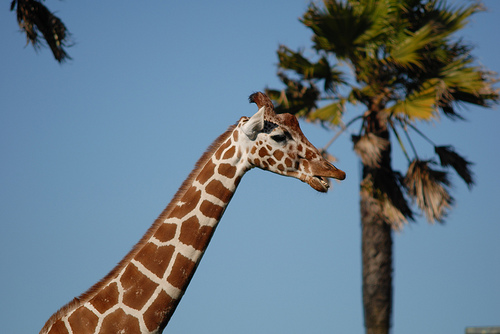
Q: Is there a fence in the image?
A: No, there are no fences.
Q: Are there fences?
A: No, there are no fences.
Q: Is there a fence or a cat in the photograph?
A: No, there are no fences or cats.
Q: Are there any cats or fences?
A: No, there are no fences or cats.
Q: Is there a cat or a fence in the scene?
A: No, there are no fences or cats.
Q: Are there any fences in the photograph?
A: No, there are no fences.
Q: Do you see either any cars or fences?
A: No, there are no fences or cars.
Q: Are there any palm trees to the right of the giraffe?
A: Yes, there is a palm tree to the right of the giraffe.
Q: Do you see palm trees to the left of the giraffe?
A: No, the palm tree is to the right of the giraffe.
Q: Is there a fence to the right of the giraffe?
A: No, there is a palm tree to the right of the giraffe.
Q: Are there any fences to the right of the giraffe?
A: No, there is a palm tree to the right of the giraffe.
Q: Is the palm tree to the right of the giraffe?
A: Yes, the palm tree is to the right of the giraffe.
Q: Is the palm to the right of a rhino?
A: No, the palm is to the right of the giraffe.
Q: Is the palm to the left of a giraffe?
A: No, the palm is to the right of a giraffe.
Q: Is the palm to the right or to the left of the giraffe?
A: The palm is to the right of the giraffe.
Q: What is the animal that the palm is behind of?
A: The animal is a giraffe.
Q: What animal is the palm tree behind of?
A: The palm is behind the giraffe.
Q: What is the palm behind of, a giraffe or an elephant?
A: The palm is behind a giraffe.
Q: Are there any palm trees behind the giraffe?
A: Yes, there is a palm tree behind the giraffe.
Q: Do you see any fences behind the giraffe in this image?
A: No, there is a palm tree behind the giraffe.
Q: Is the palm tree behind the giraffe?
A: Yes, the palm tree is behind the giraffe.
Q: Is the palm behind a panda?
A: No, the palm is behind the giraffe.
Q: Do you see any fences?
A: No, there are no fences.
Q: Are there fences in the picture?
A: No, there are no fences.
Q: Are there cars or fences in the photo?
A: No, there are no fences or cars.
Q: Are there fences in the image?
A: No, there are no fences.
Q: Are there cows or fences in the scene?
A: No, there are no fences or cows.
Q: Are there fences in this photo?
A: No, there are no fences.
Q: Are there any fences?
A: No, there are no fences.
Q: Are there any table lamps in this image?
A: No, there are no table lamps.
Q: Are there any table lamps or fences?
A: No, there are no table lamps or fences.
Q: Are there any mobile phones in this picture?
A: No, there are no mobile phones.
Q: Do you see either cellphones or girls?
A: No, there are no cellphones or girls.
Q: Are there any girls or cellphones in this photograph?
A: No, there are no cellphones or girls.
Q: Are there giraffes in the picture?
A: Yes, there is a giraffe.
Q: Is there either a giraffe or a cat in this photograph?
A: Yes, there is a giraffe.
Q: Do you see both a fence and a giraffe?
A: No, there is a giraffe but no fences.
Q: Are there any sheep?
A: No, there are no sheep.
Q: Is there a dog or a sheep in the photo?
A: No, there are no sheep or dogs.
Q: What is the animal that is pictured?
A: The animal is a giraffe.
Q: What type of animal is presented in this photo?
A: The animal is a giraffe.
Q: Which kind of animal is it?
A: The animal is a giraffe.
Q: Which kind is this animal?
A: This is a giraffe.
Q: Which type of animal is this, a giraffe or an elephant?
A: This is a giraffe.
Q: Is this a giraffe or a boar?
A: This is a giraffe.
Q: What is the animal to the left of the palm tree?
A: The animal is a giraffe.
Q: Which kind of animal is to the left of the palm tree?
A: The animal is a giraffe.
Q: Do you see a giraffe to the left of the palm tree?
A: Yes, there is a giraffe to the left of the palm tree.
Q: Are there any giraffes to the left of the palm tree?
A: Yes, there is a giraffe to the left of the palm tree.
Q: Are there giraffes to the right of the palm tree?
A: No, the giraffe is to the left of the palm tree.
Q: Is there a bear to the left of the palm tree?
A: No, there is a giraffe to the left of the palm tree.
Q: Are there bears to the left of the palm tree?
A: No, there is a giraffe to the left of the palm tree.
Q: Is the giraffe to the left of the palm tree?
A: Yes, the giraffe is to the left of the palm tree.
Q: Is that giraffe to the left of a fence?
A: No, the giraffe is to the left of the palm tree.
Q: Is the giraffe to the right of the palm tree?
A: No, the giraffe is to the left of the palm tree.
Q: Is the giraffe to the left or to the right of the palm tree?
A: The giraffe is to the left of the palm tree.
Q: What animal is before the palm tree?
A: The giraffe is in front of the palm tree.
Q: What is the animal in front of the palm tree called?
A: The animal is a giraffe.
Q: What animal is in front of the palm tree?
A: The animal is a giraffe.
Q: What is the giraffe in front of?
A: The giraffe is in front of the palm.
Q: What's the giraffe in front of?
A: The giraffe is in front of the palm.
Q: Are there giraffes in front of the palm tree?
A: Yes, there is a giraffe in front of the palm tree.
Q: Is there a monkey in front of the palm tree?
A: No, there is a giraffe in front of the palm tree.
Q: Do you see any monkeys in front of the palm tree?
A: No, there is a giraffe in front of the palm tree.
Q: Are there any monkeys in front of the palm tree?
A: No, there is a giraffe in front of the palm tree.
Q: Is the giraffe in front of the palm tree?
A: Yes, the giraffe is in front of the palm tree.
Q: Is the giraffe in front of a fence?
A: No, the giraffe is in front of the palm tree.